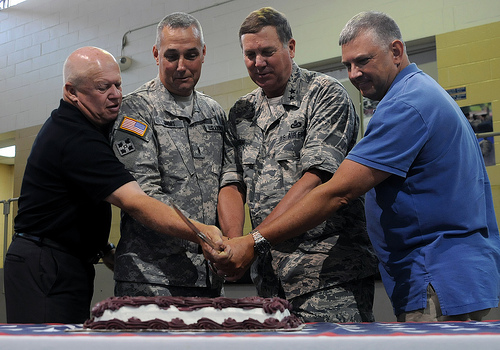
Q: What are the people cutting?
A: A cake.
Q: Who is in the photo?
A: People.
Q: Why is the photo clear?
A: The area is lit.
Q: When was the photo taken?
A: Daytime.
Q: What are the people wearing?
A: Clothes.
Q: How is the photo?
A: Clear.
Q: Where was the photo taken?
A: In an auditorium.